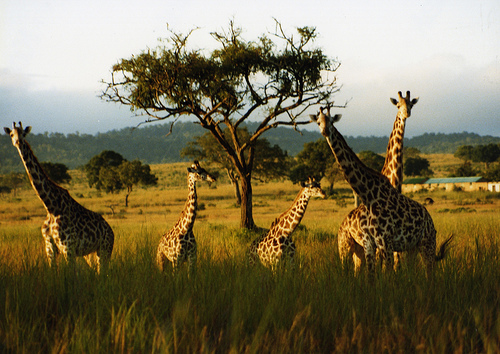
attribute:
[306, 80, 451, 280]
giraffes — standing up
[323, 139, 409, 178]
necks — crossed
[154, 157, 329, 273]
giraffes — looking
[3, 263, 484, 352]
grass — high, textured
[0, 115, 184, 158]
green hills — background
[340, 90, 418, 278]
giraffe — large, adult, standing, brown, white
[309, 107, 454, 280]
giraffe — standing, large, adult, brown, white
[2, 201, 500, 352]
grass — tall, green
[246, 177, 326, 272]
giraffe — small, young, standing, baby, brown, white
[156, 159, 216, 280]
giraffe — small, young, standing, baby, brown, white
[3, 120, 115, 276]
giraffe — large, adult, standing, brown, white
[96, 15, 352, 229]
tree — tall, leafy, green, scraggly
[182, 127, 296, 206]
tree — leafy, green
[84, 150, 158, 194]
tree — leafy, green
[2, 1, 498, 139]
sky — hazy, blue, dim, cloudy, sunny